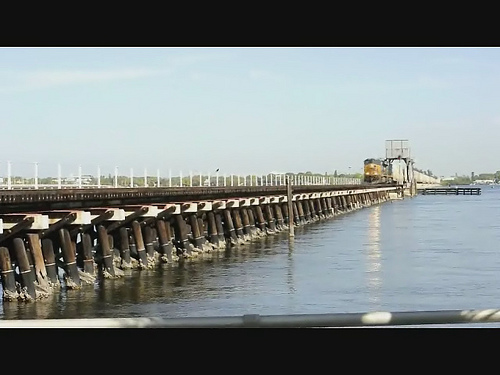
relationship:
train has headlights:
[364, 155, 445, 185] [363, 169, 379, 178]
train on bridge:
[363, 153, 440, 204] [15, 166, 316, 293]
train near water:
[364, 155, 445, 185] [382, 202, 497, 290]